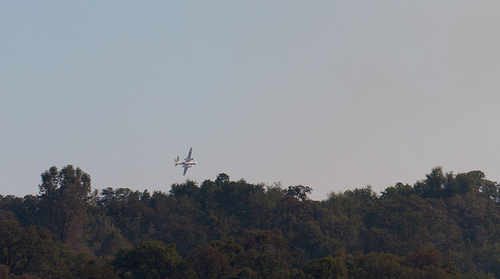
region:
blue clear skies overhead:
[191, 60, 271, 121]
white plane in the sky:
[151, 136, 217, 168]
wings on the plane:
[178, 143, 199, 160]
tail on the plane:
[161, 148, 182, 170]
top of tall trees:
[236, 165, 349, 227]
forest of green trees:
[30, 143, 440, 249]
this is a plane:
[160, 145, 207, 177]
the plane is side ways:
[162, 139, 211, 185]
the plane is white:
[165, 140, 203, 179]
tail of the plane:
[166, 151, 186, 173]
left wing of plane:
[185, 145, 196, 159]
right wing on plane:
[175, 162, 192, 177]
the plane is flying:
[20, 23, 452, 252]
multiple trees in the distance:
[25, 140, 465, 276]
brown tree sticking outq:
[20, 143, 110, 248]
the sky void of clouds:
[5, 7, 487, 267]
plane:
[158, 131, 200, 175]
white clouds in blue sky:
[341, 85, 391, 120]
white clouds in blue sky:
[248, 75, 278, 107]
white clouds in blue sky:
[425, 58, 485, 95]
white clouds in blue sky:
[61, 72, 99, 124]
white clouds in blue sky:
[265, 52, 286, 90]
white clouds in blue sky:
[121, 39, 155, 60]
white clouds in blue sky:
[287, 108, 318, 129]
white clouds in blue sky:
[250, 75, 304, 137]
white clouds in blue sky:
[444, 75, 479, 99]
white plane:
[161, 145, 202, 177]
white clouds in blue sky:
[424, 36, 448, 61]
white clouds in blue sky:
[307, 33, 341, 87]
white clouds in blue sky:
[174, 8, 195, 49]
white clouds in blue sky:
[285, 121, 305, 142]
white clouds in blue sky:
[52, 45, 133, 99]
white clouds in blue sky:
[115, 115, 139, 145]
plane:
[150, 128, 197, 178]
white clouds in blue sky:
[37, 8, 82, 55]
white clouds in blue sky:
[138, 5, 192, 65]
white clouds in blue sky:
[320, 42, 375, 102]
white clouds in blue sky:
[140, 29, 167, 64]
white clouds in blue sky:
[208, 43, 285, 103]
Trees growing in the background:
[180, 197, 305, 254]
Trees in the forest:
[164, 198, 299, 253]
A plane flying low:
[144, 132, 207, 188]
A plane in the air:
[172, 144, 211, 189]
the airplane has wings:
[173, 145, 197, 175]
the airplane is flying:
[174, 147, 196, 177]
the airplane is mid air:
[173, 146, 196, 176]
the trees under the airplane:
[0, 145, 499, 277]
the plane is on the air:
[173, 143, 197, 175]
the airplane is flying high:
[171, 145, 203, 179]